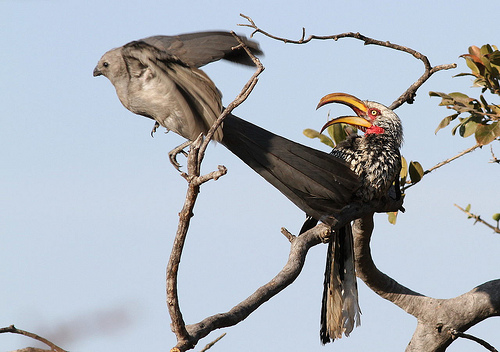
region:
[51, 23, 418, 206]
birds on a tree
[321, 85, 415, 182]
scary looking bird on tree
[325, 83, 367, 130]
yellow beak of bird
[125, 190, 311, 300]
branches on the tree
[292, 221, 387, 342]
tail feather of animal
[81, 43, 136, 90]
head of the bird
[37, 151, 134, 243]
blue sky above birds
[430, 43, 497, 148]
leaves on tree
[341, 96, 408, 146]
red faced bird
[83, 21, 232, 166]
bird flying off the branch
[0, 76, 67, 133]
part of the sky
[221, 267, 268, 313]
part of a branch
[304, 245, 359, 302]
part of a tail wing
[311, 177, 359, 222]
part of a feather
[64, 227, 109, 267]
part of the sky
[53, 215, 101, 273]
part of the sky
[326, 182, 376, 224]
edge of a wing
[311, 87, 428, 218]
bird with a large yellow beak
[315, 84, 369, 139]
curved yellow beak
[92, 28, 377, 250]
gray bird with long tail feathers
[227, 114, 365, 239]
gray tail feather of a bird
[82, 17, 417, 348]
two birds in a tree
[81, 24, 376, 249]
gray bird taking off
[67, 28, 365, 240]
gray bird about to fly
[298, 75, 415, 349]
gray and white bird with tail feathers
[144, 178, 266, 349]
bare tree branches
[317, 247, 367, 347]
white and black tail feathers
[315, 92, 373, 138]
A large orange beak on a bird.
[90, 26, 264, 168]
An all gray colored bird.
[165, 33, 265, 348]
Thin branch a gray bird is sitting on.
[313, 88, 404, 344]
An orange beaked bird with a long tail.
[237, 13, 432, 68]
Thin branch above a orange beaked bird.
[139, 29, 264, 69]
A wing of a gray bird that is sticking up.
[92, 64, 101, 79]
Gray beak on a gray bird.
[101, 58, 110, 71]
Black eyeball on a gray bird.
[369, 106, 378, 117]
Small white and black eye of a bird.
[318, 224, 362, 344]
Long gray and black tail end of a bird.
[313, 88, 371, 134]
long, pointed, yellow beak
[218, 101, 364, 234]
long black feathers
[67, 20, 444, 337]
two birds on a tree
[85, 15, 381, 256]
grey bird with a long tail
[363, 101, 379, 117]
small round eye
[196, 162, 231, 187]
short and skinny branch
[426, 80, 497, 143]
bunch of green leaves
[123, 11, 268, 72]
grey wing in motion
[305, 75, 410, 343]
black, white, and red bird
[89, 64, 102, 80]
tiny pointed black beak